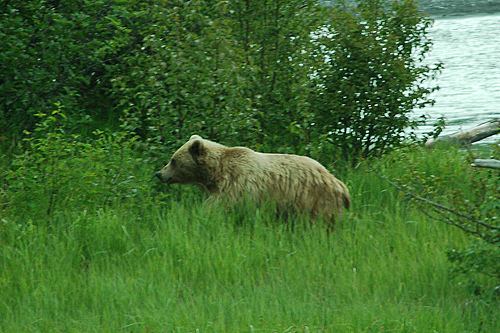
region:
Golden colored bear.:
[157, 133, 357, 233]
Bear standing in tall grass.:
[20, 135, 490, 326]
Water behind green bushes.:
[93, 2, 498, 142]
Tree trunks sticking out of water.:
[429, 110, 495, 182]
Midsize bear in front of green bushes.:
[4, 0, 431, 242]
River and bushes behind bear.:
[132, 3, 497, 253]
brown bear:
[142, 140, 356, 230]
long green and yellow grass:
[195, 303, 236, 329]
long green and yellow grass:
[295, 230, 357, 275]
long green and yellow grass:
[372, 260, 395, 282]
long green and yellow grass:
[182, 282, 232, 310]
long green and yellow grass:
[110, 246, 147, 279]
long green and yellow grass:
[133, 280, 193, 308]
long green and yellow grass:
[230, 283, 283, 322]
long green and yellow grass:
[359, 230, 404, 273]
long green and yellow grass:
[158, 273, 198, 305]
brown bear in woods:
[173, 138, 345, 238]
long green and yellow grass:
[100, 264, 140, 285]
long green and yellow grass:
[299, 264, 338, 285]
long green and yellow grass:
[378, 251, 419, 278]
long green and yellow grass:
[184, 256, 216, 287]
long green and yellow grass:
[72, 240, 124, 281]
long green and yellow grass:
[87, 206, 151, 254]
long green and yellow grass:
[236, 269, 266, 300]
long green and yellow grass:
[326, 266, 375, 303]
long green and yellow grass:
[218, 249, 251, 278]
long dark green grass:
[151, 257, 191, 292]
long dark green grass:
[314, 286, 360, 322]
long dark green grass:
[396, 257, 426, 293]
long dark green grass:
[176, 274, 223, 329]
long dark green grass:
[93, 240, 176, 311]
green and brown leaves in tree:
[138, 84, 215, 141]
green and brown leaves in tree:
[236, 54, 291, 92]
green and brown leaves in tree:
[173, 54, 198, 86]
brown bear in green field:
[149, 134, 352, 231]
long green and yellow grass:
[338, 259, 376, 293]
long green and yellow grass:
[147, 240, 192, 289]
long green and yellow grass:
[34, 211, 79, 268]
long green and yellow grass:
[121, 224, 161, 257]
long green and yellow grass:
[369, 264, 401, 314]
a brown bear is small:
[146, 123, 360, 236]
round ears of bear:
[181, 126, 207, 158]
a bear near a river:
[153, 11, 498, 224]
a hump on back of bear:
[183, 124, 264, 169]